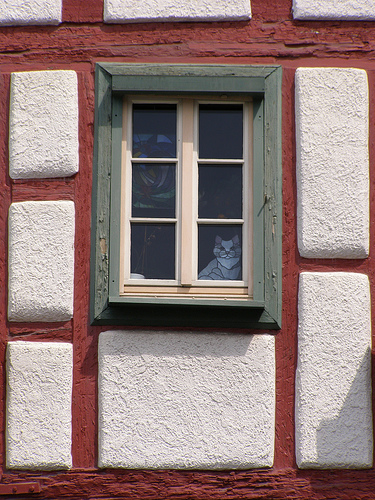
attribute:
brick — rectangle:
[295, 67, 368, 258]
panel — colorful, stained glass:
[128, 130, 178, 206]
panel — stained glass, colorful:
[199, 232, 242, 278]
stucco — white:
[111, 329, 265, 457]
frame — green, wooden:
[92, 52, 288, 97]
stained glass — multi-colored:
[131, 132, 176, 213]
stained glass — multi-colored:
[200, 222, 242, 278]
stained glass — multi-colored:
[130, 224, 172, 279]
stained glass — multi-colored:
[199, 163, 240, 217]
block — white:
[290, 51, 373, 286]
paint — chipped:
[262, 190, 279, 269]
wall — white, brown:
[0, 0, 374, 498]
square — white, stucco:
[8, 68, 78, 183]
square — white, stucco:
[94, 327, 274, 468]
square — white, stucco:
[4, 340, 74, 473]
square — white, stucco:
[295, 268, 374, 470]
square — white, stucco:
[293, 65, 369, 257]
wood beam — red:
[13, 0, 298, 84]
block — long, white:
[296, 273, 373, 469]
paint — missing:
[96, 233, 109, 258]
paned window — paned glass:
[109, 88, 264, 298]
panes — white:
[134, 116, 229, 222]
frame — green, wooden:
[87, 61, 280, 327]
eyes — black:
[208, 231, 238, 279]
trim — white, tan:
[121, 95, 254, 298]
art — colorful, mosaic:
[132, 128, 184, 213]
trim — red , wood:
[4, 2, 373, 497]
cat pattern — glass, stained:
[197, 235, 241, 282]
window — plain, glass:
[122, 97, 248, 286]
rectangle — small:
[5, 338, 73, 470]